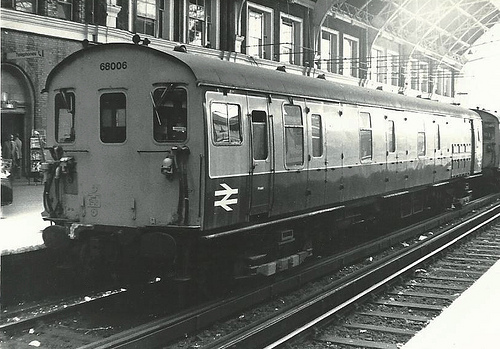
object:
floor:
[282, 103, 305, 127]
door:
[93, 82, 147, 226]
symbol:
[214, 182, 240, 211]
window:
[210, 101, 244, 146]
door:
[247, 93, 274, 220]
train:
[475, 103, 499, 185]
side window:
[251, 109, 268, 161]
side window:
[358, 110, 374, 162]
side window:
[385, 118, 396, 153]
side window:
[414, 132, 425, 156]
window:
[99, 91, 127, 145]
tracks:
[323, 237, 447, 347]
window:
[149, 81, 191, 145]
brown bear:
[37, 35, 500, 241]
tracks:
[0, 174, 497, 349]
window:
[359, 111, 374, 162]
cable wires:
[233, 41, 320, 54]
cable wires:
[287, 53, 432, 63]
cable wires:
[318, 63, 453, 67]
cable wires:
[336, 66, 461, 72]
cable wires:
[362, 75, 477, 80]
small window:
[96, 87, 130, 145]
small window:
[53, 87, 76, 145]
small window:
[311, 113, 323, 158]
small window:
[433, 120, 445, 153]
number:
[98, 61, 128, 71]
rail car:
[39, 33, 500, 302]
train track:
[264, 272, 375, 349]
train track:
[43, 291, 181, 346]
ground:
[0, 223, 500, 349]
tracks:
[226, 202, 500, 349]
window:
[251, 109, 268, 161]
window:
[211, 102, 270, 159]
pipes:
[39, 145, 75, 218]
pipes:
[159, 145, 191, 226]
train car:
[41, 32, 277, 291]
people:
[3, 132, 24, 177]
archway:
[0, 162, 68, 257]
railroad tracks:
[0, 192, 500, 349]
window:
[283, 103, 304, 125]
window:
[282, 102, 304, 170]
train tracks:
[0, 170, 494, 346]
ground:
[0, 179, 490, 348]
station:
[0, 10, 323, 257]